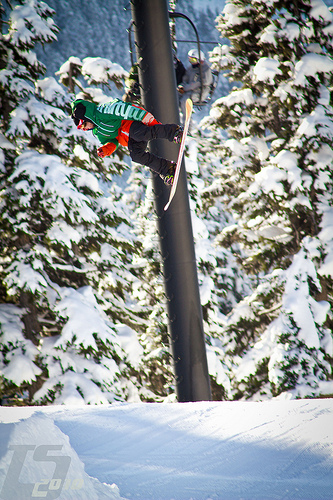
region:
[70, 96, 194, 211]
snowboarder snowboarding through air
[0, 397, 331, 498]
white snow covered ground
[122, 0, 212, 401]
large black ski lift pole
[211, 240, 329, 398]
white snow covered tree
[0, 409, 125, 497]
pile of white snow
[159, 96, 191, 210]
white and orange snow board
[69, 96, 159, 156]
green and red jacket on snowboarder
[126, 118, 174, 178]
black snow pants on snow boarder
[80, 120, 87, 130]
sun glasses on snow boarder's face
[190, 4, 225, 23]
Trees in the background.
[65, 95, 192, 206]
A snow boarder does a trick.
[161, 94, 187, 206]
A snow board.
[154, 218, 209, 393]
A high pole.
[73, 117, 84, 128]
Snowboarder's goggles.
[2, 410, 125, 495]
A pile of snow.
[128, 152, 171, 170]
The black snow pants.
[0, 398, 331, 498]
Ground covered with snow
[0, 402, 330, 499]
White snow on the ground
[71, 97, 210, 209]
Person on a snowboard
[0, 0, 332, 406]
Trees covered with snow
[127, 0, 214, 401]
Gray pole on snow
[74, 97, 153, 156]
Green and red jacket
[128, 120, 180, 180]
Man wearing black pants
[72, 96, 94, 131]
Man wearing green hood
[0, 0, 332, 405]
Trees growing on snow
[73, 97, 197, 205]
a kid in a green jacket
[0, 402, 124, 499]
a large mound of snow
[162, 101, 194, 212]
a white snowboard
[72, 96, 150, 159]
a puffy green snow jacket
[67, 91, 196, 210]
a kid in a jacket doing a trick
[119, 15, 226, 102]
a group of people on a ski lift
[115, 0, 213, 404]
a tall black metal pole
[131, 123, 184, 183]
a pair of black snow pants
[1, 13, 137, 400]
a tall snow covered tree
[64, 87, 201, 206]
a snowboarder getting a ton of air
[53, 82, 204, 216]
a snowboarder is in the air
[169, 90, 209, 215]
this is a snowboard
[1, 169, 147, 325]
snow is on the branches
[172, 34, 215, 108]
a person is on a ski lift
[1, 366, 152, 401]
snow is on a pine tree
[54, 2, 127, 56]
mountainside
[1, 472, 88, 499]
website logo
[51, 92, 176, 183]
male snowboarder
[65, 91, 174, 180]
man jumping with snowboard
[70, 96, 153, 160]
puffy green winter jacket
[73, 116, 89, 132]
red snow goggles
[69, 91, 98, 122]
green hood on head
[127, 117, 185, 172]
black puffy snow pants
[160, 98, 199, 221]
white snowboard bottom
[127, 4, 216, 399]
large wide black metal pole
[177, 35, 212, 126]
person sitting on ski lift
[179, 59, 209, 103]
gray winter jacket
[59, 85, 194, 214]
person on a snowboard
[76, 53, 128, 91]
snow on a tree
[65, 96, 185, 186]
boy wearing green jacket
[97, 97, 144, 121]
white letters on green jacket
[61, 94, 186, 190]
boy wearing black pants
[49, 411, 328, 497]
shadow on the snow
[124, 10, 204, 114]
ski lift behind the pole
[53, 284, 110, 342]
snow on a tree branch